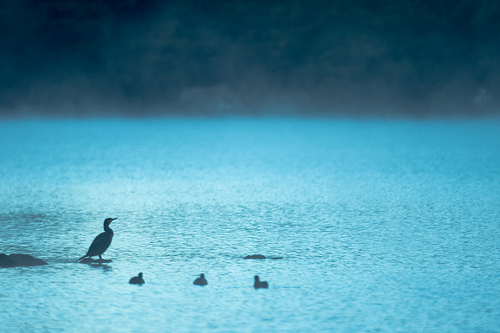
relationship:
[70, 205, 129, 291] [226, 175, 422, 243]
duck by water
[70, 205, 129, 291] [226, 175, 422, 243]
duck sitting in water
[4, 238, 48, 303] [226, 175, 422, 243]
rock in water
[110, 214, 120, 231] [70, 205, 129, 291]
beak of duck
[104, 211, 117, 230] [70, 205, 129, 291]
head of duck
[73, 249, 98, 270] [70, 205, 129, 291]
tail of duck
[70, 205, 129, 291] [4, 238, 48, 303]
duck on rock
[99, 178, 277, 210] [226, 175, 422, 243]
reflection on water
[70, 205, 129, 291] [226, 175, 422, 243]
duck in water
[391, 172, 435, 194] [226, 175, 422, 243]
ripples in water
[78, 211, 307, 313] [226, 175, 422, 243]
ducks in water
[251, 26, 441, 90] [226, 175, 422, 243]
trees behind water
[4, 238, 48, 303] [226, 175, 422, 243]
rock protruding from water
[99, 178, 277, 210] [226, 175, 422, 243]
reflection off water